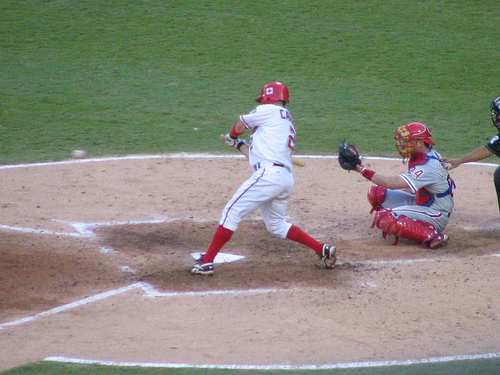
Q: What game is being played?
A: Baseball.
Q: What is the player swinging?
A: A bat.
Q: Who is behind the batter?
A: The catcher.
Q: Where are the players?
A: The field.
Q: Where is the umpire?
A: Behind the catcher.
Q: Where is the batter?
A: On home base.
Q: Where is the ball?
A: In the air.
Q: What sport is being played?
A: Baseball.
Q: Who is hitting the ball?
A: The batter.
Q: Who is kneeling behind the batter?
A: The catcher.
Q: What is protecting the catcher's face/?
A: A mask.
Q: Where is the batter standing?
A: The batter's box.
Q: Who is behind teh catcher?
A: The umpire.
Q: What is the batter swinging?
A: A bat.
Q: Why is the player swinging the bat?
A: To hit a ball.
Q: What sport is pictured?
A: Baseball.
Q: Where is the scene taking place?
A: On a baseball field.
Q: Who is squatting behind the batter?
A: The catcher.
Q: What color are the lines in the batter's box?
A: White.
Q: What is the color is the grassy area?
A: Green.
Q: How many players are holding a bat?
A: 1.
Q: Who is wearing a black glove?
A: The catcher.